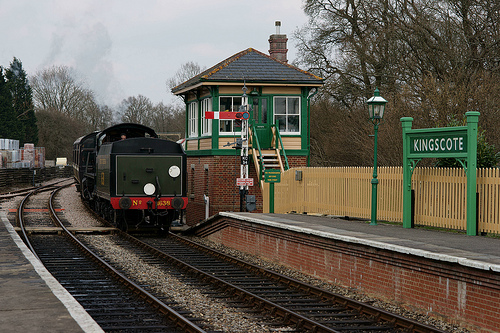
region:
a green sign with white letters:
[395, 119, 480, 167]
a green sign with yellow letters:
[263, 165, 280, 188]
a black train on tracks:
[51, 107, 222, 237]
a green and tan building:
[158, 50, 343, 183]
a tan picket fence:
[257, 166, 499, 250]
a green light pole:
[340, 79, 402, 219]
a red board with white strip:
[201, 105, 258, 130]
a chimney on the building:
[256, 25, 311, 86]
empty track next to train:
[12, 169, 138, 332]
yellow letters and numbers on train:
[113, 190, 185, 210]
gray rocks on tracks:
[170, 282, 213, 313]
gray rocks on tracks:
[196, 292, 242, 327]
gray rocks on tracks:
[174, 280, 204, 301]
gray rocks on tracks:
[143, 271, 180, 288]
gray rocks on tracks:
[151, 267, 181, 294]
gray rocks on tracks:
[134, 258, 164, 287]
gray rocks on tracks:
[136, 253, 157, 280]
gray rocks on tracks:
[108, 244, 142, 269]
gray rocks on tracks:
[86, 228, 116, 255]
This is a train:
[57, 117, 198, 237]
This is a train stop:
[172, 66, 497, 284]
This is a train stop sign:
[380, 112, 490, 242]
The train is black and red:
[72, 113, 189, 216]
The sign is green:
[395, 117, 481, 237]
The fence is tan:
[267, 155, 499, 229]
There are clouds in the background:
[2, 8, 145, 125]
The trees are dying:
[295, 2, 498, 169]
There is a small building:
[165, 45, 317, 227]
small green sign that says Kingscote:
[391, 105, 492, 237]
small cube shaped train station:
[193, 15, 314, 196]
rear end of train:
[60, 113, 196, 231]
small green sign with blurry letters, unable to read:
[260, 163, 288, 214]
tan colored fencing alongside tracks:
[286, 163, 497, 228]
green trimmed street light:
[353, 83, 395, 234]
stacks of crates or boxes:
[2, 131, 67, 172]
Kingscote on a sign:
[411, 135, 462, 155]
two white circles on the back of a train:
[138, 159, 183, 198]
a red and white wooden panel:
[203, 110, 241, 120]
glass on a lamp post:
[368, 96, 384, 116]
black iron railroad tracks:
[4, 183, 465, 330]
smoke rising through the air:
[37, 17, 119, 112]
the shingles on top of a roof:
[166, 49, 326, 92]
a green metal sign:
[397, 111, 480, 239]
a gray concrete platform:
[219, 196, 499, 280]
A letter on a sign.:
[457, 136, 467, 153]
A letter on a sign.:
[453, 134, 458, 153]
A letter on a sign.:
[446, 136, 451, 152]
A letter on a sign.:
[441, 137, 446, 151]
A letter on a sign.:
[433, 139, 438, 151]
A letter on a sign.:
[429, 137, 432, 151]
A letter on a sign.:
[422, 137, 428, 149]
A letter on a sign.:
[419, 139, 422, 154]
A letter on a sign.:
[413, 137, 418, 157]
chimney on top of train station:
[269, 20, 289, 64]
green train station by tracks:
[171, 18, 326, 227]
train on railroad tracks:
[69, 121, 192, 238]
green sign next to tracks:
[399, 108, 480, 235]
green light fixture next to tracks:
[366, 88, 389, 225]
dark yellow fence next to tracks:
[259, 165, 498, 238]